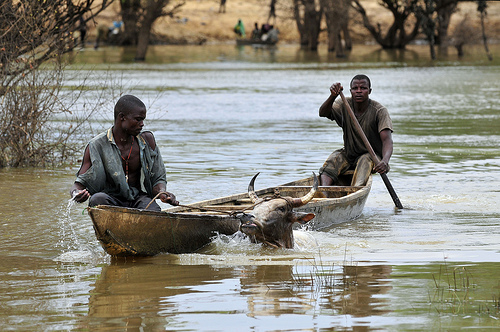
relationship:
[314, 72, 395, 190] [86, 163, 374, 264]
man rowing kayak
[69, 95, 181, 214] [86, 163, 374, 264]
man at front of kayak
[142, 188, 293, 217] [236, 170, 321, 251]
leash strapped to cow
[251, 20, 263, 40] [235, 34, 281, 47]
person loading into boat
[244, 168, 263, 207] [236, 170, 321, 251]
horn on cow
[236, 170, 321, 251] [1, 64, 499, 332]
cow inside water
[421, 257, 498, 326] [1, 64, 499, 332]
grass protruding from water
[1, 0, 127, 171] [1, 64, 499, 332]
tree protruding from water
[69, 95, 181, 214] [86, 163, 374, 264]
man inside of kayak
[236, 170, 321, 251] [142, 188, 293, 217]
cow tied on leash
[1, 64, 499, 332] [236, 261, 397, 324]
water has reflection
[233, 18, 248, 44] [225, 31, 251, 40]
person standing in grass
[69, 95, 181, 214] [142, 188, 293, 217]
man holding leash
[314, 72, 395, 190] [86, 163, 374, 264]
man paddling kayak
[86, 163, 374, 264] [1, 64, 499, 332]
kayak on top of water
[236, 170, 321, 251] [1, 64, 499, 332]
cow in water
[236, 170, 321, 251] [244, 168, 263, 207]
cow has horn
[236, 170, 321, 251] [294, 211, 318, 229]
cow has ear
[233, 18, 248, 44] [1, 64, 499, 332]
person beside water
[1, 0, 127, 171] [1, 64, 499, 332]
tree in water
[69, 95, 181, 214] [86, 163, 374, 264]
man riding in kayak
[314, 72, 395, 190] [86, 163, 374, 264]
man steering kayak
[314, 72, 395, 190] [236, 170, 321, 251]
man holding cow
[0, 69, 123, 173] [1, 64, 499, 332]
brush protruding from water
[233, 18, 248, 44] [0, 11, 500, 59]
person on shore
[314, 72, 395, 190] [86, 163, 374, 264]
man inside of kayak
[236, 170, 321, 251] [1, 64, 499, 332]
cow swimming in water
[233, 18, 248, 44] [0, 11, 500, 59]
person standing on shore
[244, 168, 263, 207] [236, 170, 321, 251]
horn on top of cow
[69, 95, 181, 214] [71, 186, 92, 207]
man has hand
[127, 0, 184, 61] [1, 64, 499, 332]
tree growing in water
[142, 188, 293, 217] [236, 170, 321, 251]
leash holding cow